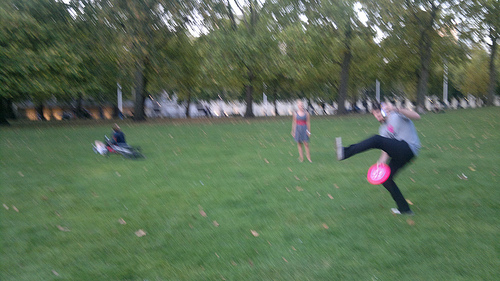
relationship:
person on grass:
[291, 98, 313, 163] [0, 105, 500, 279]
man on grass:
[335, 100, 424, 214] [0, 105, 500, 279]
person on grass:
[105, 123, 126, 150] [0, 105, 500, 279]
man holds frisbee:
[335, 100, 424, 214] [370, 162, 390, 187]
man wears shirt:
[335, 100, 424, 214] [376, 112, 421, 155]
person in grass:
[90, 123, 147, 161] [23, 177, 326, 273]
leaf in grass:
[118, 213, 131, 225] [24, 163, 486, 280]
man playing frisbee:
[326, 92, 433, 222] [360, 159, 394, 186]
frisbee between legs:
[360, 159, 394, 186] [331, 134, 420, 223]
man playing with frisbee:
[335, 100, 424, 214] [364, 162, 390, 184]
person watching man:
[291, 98, 313, 163] [335, 100, 424, 214]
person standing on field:
[291, 98, 313, 163] [1, 102, 497, 279]